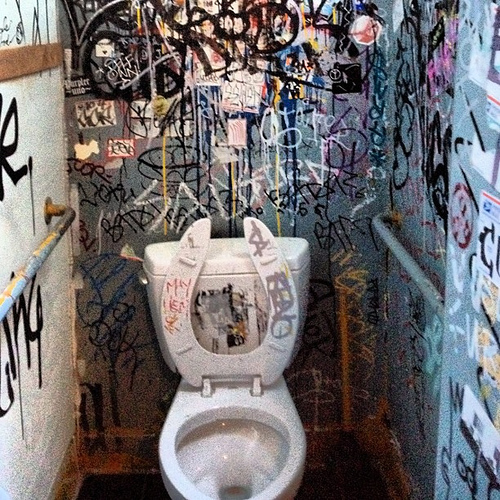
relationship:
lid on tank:
[146, 230, 315, 275] [142, 262, 316, 377]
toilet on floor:
[138, 205, 320, 498] [82, 467, 154, 499]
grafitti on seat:
[154, 216, 298, 379] [161, 214, 301, 389]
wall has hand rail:
[7, 5, 80, 494] [0, 197, 78, 324]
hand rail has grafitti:
[0, 197, 78, 324] [2, 271, 44, 422]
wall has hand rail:
[78, 2, 499, 412] [373, 221, 443, 314]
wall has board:
[2, 5, 80, 493] [1, 32, 68, 84]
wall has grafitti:
[115, 77, 365, 164] [68, 7, 390, 238]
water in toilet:
[222, 470, 250, 497] [138, 205, 320, 498]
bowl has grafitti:
[159, 399, 306, 497] [192, 284, 254, 352]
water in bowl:
[222, 470, 250, 497] [174, 406, 292, 498]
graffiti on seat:
[67, 0, 380, 235] [135, 237, 292, 394]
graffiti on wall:
[67, 3, 381, 238] [59, 1, 377, 495]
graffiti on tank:
[186, 280, 262, 352] [137, 232, 323, 372]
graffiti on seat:
[264, 271, 294, 342] [161, 214, 301, 389]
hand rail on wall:
[0, 197, 78, 324] [17, 132, 73, 200]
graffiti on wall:
[67, 0, 380, 235] [82, 4, 388, 217]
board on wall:
[1, 40, 61, 82] [2, 5, 80, 493]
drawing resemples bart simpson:
[419, 382, 489, 499] [433, 351, 493, 498]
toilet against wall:
[138, 205, 320, 498] [57, 7, 424, 496]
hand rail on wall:
[0, 197, 78, 324] [2, 5, 80, 493]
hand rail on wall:
[373, 221, 443, 314] [370, 0, 461, 498]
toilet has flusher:
[138, 205, 320, 500] [130, 264, 151, 291]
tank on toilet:
[144, 238, 309, 372] [132, 211, 307, 496]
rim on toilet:
[278, 421, 310, 481] [138, 205, 320, 498]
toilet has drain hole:
[138, 205, 320, 498] [214, 478, 255, 500]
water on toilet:
[222, 470, 250, 497] [132, 211, 307, 496]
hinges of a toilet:
[191, 370, 273, 412] [132, 211, 307, 496]